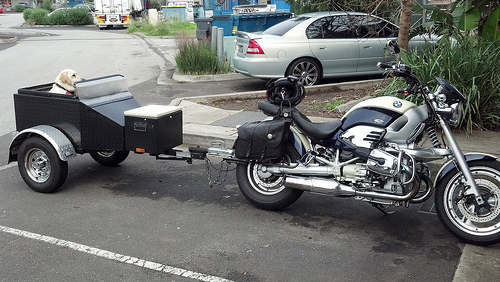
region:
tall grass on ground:
[409, 49, 434, 77]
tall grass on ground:
[456, 78, 492, 132]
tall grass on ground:
[453, 42, 477, 82]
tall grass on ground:
[479, 32, 498, 98]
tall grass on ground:
[205, 43, 230, 70]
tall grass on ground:
[182, 45, 201, 68]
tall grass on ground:
[170, 13, 209, 50]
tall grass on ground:
[137, 11, 169, 51]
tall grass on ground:
[34, 0, 57, 32]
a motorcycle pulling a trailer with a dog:
[10, 39, 498, 244]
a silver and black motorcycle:
[231, 39, 498, 245]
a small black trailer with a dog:
[6, 68, 209, 202]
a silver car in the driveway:
[230, 12, 458, 87]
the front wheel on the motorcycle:
[433, 162, 498, 246]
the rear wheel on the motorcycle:
[234, 142, 304, 212]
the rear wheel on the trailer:
[15, 137, 67, 193]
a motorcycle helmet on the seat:
[265, 77, 305, 106]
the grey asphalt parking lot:
[0, 134, 498, 280]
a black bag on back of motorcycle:
[233, 120, 289, 160]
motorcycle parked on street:
[231, 65, 479, 229]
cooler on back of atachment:
[125, 91, 197, 148]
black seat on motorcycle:
[267, 93, 347, 144]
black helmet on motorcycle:
[274, 78, 308, 102]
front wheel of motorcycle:
[428, 148, 498, 238]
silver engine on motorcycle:
[287, 145, 398, 195]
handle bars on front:
[381, 53, 428, 88]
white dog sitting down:
[37, 63, 89, 100]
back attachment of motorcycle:
[0, 33, 201, 177]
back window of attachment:
[85, 72, 140, 99]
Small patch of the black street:
[118, 218, 157, 244]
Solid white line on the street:
[61, 231, 85, 257]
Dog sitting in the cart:
[53, 70, 84, 89]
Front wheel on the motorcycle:
[434, 163, 499, 243]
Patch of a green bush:
[178, 43, 218, 76]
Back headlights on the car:
[247, 41, 261, 57]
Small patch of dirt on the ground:
[228, 98, 238, 110]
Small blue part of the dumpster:
[218, 19, 235, 27]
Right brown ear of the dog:
[61, 72, 69, 86]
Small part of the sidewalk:
[198, 109, 207, 122]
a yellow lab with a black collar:
[39, 64, 87, 96]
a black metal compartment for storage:
[118, 101, 189, 157]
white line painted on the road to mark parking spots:
[4, 220, 222, 280]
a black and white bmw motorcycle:
[233, 39, 498, 245]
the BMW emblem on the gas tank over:
[389, 98, 410, 110]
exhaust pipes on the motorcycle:
[264, 160, 435, 200]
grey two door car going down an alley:
[225, 7, 469, 87]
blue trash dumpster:
[193, 5, 302, 37]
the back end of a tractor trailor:
[84, 0, 154, 29]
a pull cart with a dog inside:
[5, 70, 215, 193]